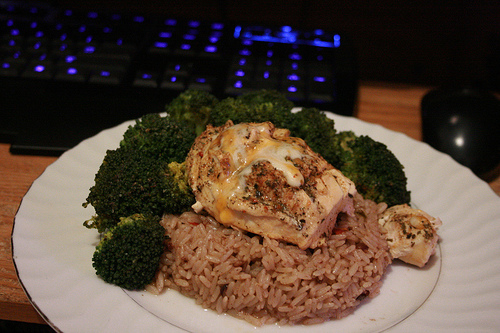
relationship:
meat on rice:
[190, 119, 347, 241] [178, 213, 344, 315]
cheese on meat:
[221, 131, 309, 193] [190, 119, 347, 241]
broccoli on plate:
[97, 150, 176, 258] [36, 163, 200, 315]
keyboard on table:
[49, 22, 374, 109] [2, 147, 78, 333]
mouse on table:
[415, 79, 494, 178] [2, 147, 78, 333]